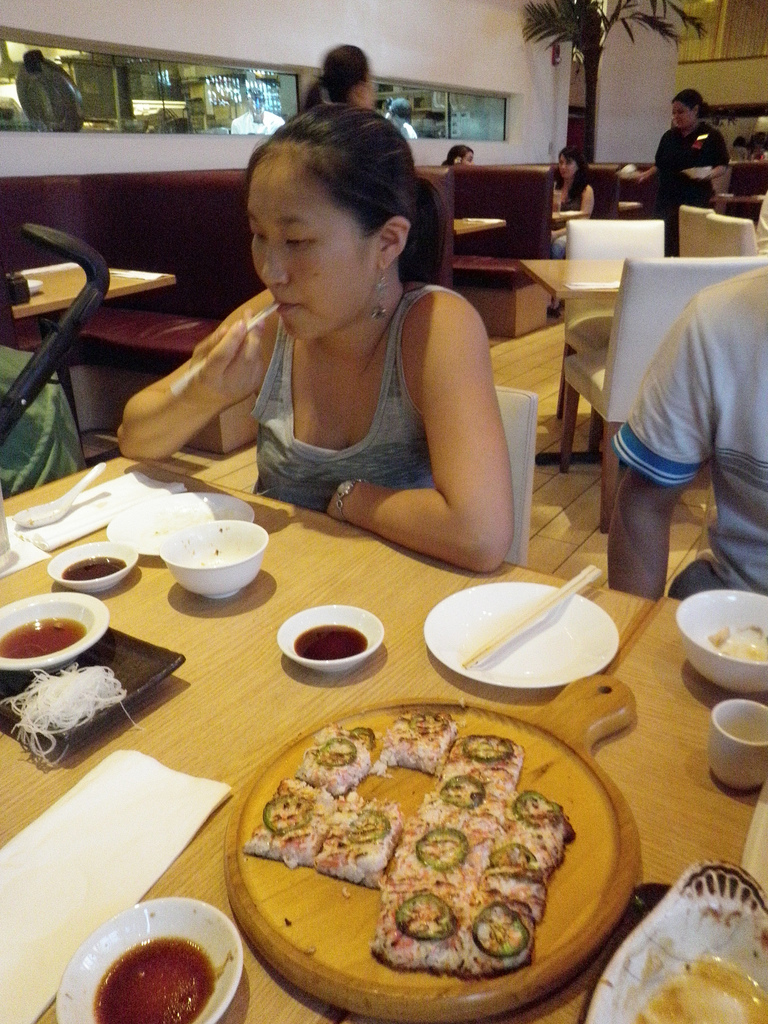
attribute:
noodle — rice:
[3, 666, 137, 769]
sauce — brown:
[298, 625, 366, 655]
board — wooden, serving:
[226, 674, 647, 1016]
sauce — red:
[120, 961, 223, 1018]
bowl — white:
[54, 880, 220, 1005]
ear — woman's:
[347, 203, 432, 288]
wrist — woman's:
[330, 479, 362, 520]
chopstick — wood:
[460, 556, 595, 660]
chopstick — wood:
[469, 566, 605, 670]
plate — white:
[420, 580, 619, 688]